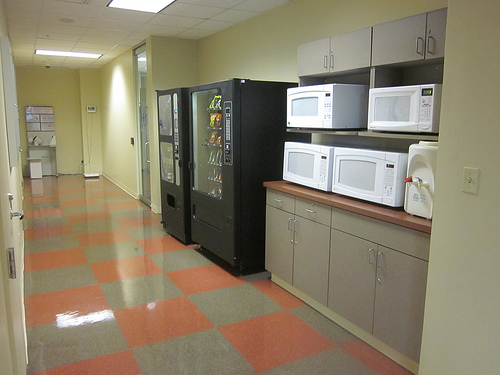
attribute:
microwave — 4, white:
[285, 79, 367, 131]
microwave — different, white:
[368, 83, 439, 134]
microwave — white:
[281, 139, 334, 193]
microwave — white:
[330, 145, 409, 212]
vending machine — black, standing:
[156, 81, 188, 246]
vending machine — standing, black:
[187, 78, 299, 278]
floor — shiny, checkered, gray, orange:
[23, 174, 418, 373]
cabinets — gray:
[265, 5, 448, 375]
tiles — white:
[4, 1, 291, 71]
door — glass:
[192, 85, 223, 202]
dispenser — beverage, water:
[402, 140, 439, 223]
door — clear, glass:
[134, 44, 152, 211]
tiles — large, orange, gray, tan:
[25, 175, 418, 374]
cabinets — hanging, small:
[298, 5, 447, 77]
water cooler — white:
[403, 138, 439, 220]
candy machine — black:
[188, 79, 300, 276]